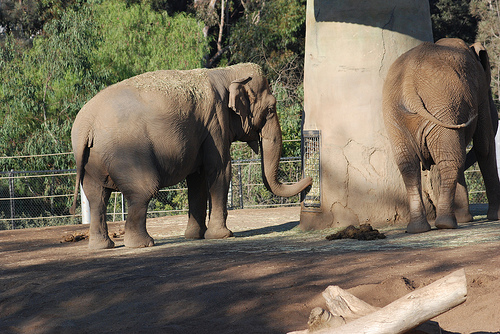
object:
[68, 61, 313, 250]
elephant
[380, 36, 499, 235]
elephant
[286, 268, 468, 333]
branch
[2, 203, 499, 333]
ground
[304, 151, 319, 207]
hay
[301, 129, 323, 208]
feeder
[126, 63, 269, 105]
hay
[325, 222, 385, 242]
dung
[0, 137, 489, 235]
fence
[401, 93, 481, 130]
tail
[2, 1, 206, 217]
tree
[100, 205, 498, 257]
hay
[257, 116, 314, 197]
trunk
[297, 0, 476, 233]
pillar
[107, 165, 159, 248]
leg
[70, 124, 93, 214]
tail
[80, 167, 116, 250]
hind leg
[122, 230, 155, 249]
foot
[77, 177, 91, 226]
pole